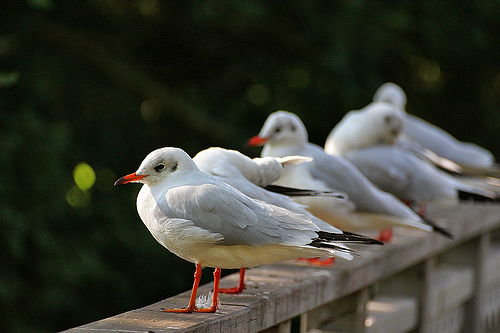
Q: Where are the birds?
A: On wood rail.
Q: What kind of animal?
A: Bird.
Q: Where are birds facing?
A: Left.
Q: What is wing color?
A: Grey.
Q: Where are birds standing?
A: Ledge.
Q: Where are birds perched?
A: Railing.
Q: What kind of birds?
A: Seagulls.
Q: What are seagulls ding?
A: Looking for food.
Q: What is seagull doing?
A: Resting.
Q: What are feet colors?
A: Orange.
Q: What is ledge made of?
A: Wood.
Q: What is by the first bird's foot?
A: A feather.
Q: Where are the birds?
A: On the railing.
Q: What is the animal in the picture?
A: Birds.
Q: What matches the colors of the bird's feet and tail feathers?
A: Its beak.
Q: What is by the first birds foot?
A: A feather.